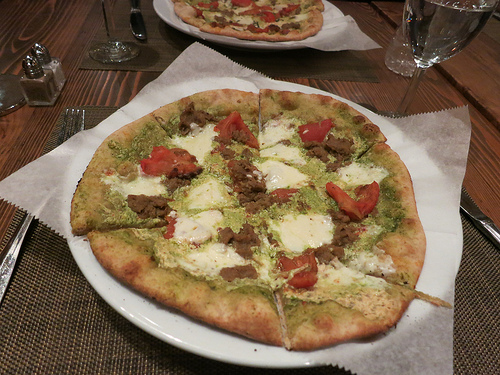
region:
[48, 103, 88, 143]
fork tines at the table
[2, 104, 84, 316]
fork on the placemat partically covered by wax paper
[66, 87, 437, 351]
pizza sitting on paper and plate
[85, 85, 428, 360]
the sauce on the pizza is pesto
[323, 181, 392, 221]
chunks of tomatos are one of the toppings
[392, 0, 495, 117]
a glass filled with water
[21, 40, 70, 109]
salt and peper shaker on the left side of the fork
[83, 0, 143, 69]
stem of water glass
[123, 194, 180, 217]
hamburger is one of the other toppings on the pizza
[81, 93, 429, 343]
goat cheese is the possible third topping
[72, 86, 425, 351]
a whole pizza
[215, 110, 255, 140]
a tomato on top of pizza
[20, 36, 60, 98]
small salt and pepper shakers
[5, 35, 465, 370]
piece of wax paper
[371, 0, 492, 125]
a tall clear glass cup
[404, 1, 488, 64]
the water in the cup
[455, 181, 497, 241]
a shiny butter knife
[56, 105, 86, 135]
the top of a fork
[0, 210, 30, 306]
the shiny silver fork handle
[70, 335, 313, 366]
the edge of the white plate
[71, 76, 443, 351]
gourmet pizza in six slices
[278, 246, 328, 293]
chunk of tomato on a pizza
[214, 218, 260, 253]
sausage on a pizzas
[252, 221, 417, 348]
slice of goat cheese pizza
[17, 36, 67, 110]
salt and pepper shakers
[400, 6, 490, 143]
empty wine glass on the table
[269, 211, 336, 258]
splotch of goat cheese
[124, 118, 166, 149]
green sauce on a goat cheese pizza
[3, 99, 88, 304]
fork on a placemet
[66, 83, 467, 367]
pizza on a round plate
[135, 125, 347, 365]
A pizza is visible.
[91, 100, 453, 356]
six slices of pizza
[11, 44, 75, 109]
salt and pepper shaker on table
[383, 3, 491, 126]
glass of wine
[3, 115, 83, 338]
fork utensil for pizza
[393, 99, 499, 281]
knife utensil for pizza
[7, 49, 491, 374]
plastic paper under pizza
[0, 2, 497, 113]
wooden table at dinner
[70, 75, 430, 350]
thin crusted pizza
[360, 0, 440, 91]
bottle of water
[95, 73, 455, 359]
sausage and tomato pizza